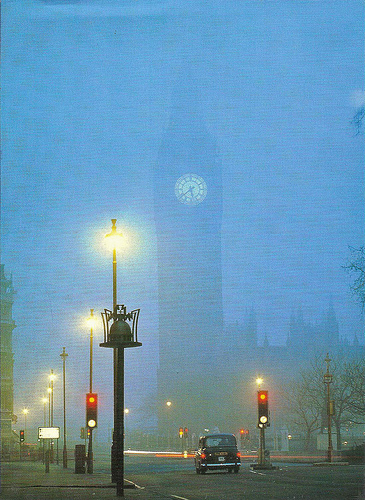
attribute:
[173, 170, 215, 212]
clock — lit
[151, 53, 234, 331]
tower — tall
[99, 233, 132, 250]
light — lighted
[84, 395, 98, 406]
light — red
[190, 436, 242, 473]
car — black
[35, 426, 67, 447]
sign — white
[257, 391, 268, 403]
light — grouped